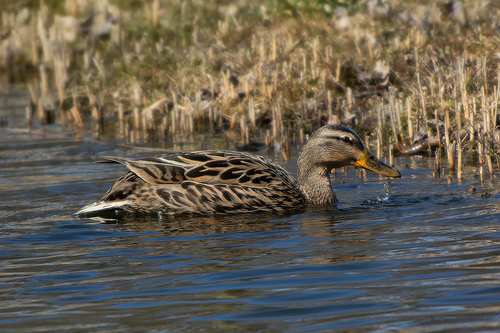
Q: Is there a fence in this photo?
A: No, there are no fences.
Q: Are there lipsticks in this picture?
A: No, there are no lipsticks.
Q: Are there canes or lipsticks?
A: No, there are no lipsticks or canes.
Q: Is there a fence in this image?
A: No, there are no fences.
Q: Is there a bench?
A: No, there are no benches.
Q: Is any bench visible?
A: No, there are no benches.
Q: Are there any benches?
A: No, there are no benches.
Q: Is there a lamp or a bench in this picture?
A: No, there are no benches or lamps.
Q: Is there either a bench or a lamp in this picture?
A: No, there are no benches or lamps.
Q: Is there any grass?
A: Yes, there is grass.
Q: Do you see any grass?
A: Yes, there is grass.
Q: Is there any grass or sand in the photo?
A: Yes, there is grass.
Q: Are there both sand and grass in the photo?
A: No, there is grass but no sand.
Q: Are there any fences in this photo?
A: No, there are no fences.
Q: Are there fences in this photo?
A: No, there are no fences.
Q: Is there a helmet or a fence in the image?
A: No, there are no fences or helmets.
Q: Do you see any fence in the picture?
A: No, there are no fences.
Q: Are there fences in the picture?
A: No, there are no fences.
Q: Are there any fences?
A: No, there are no fences.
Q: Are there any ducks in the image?
A: Yes, there is a duck.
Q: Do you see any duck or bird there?
A: Yes, there is a duck.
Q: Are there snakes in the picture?
A: No, there are no snakes.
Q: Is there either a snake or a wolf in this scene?
A: No, there are no snakes or wolves.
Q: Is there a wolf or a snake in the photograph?
A: No, there are no snakes or wolves.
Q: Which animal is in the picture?
A: The animal is a duck.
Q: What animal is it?
A: The animal is a duck.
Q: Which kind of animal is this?
A: This is a duck.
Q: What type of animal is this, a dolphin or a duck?
A: This is a duck.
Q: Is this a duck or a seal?
A: This is a duck.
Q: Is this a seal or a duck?
A: This is a duck.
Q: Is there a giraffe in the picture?
A: No, there are no giraffes.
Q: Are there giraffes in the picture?
A: No, there are no giraffes.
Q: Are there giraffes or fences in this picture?
A: No, there are no giraffes or fences.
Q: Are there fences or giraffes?
A: No, there are no giraffes or fences.